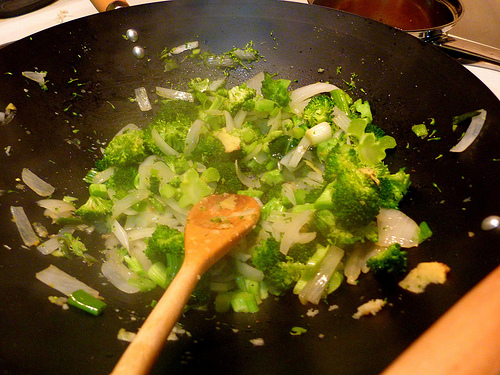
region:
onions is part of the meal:
[86, 70, 428, 319]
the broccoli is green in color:
[325, 158, 375, 225]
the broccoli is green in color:
[108, 127, 153, 167]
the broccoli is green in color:
[197, 135, 240, 202]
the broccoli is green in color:
[149, 227, 184, 274]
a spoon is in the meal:
[104, 194, 264, 373]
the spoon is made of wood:
[97, 187, 267, 369]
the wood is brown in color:
[101, 195, 260, 374]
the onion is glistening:
[302, 241, 344, 306]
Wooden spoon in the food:
[106, 190, 262, 374]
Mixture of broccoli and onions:
[171, 101, 363, 183]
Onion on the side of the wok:
[452, 108, 488, 153]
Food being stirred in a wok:
[93, 78, 407, 301]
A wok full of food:
[3, 0, 480, 359]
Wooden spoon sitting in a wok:
[109, 192, 260, 367]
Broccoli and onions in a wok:
[86, 84, 396, 290]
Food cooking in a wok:
[83, 84, 411, 311]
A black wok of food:
[3, 5, 490, 362]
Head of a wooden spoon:
[184, 180, 259, 268]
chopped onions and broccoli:
[0, 40, 485, 345]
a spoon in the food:
[110, 194, 259, 374]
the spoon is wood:
[110, 192, 259, 373]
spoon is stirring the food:
[107, 195, 256, 373]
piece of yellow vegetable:
[400, 260, 448, 295]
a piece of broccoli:
[334, 168, 379, 229]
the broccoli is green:
[145, 225, 182, 273]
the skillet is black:
[0, 0, 499, 374]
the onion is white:
[450, 108, 486, 150]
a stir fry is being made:
[73, 78, 372, 292]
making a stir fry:
[65, 69, 430, 331]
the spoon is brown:
[117, 192, 269, 327]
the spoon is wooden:
[111, 178, 263, 368]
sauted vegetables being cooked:
[25, 42, 412, 358]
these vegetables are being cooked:
[30, 73, 474, 352]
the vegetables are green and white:
[102, 97, 398, 298]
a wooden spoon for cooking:
[75, 201, 278, 368]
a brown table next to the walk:
[370, 260, 495, 374]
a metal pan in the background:
[335, 1, 471, 55]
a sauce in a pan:
[346, 0, 465, 42]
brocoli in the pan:
[80, 63, 447, 320]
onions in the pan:
[130, 83, 367, 112]